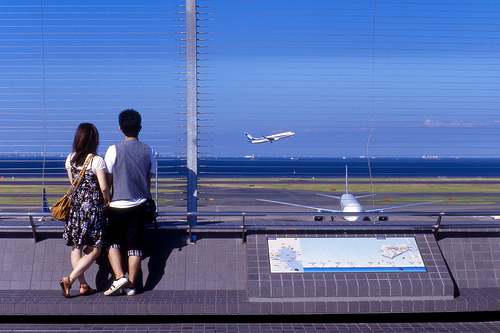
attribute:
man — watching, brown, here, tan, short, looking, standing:
[99, 99, 182, 272]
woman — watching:
[42, 108, 116, 298]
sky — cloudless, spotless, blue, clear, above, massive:
[65, 9, 264, 96]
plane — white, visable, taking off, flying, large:
[242, 115, 307, 162]